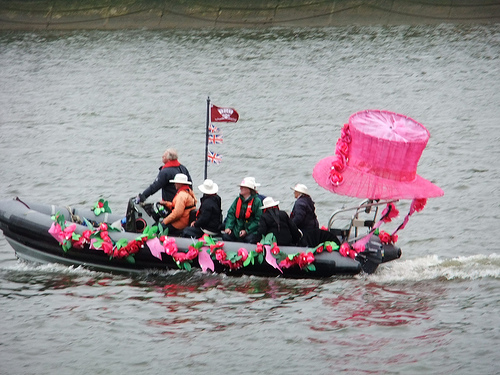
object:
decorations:
[47, 209, 357, 274]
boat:
[0, 190, 402, 277]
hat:
[169, 173, 193, 185]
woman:
[160, 173, 197, 237]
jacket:
[163, 185, 197, 230]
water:
[0, 25, 500, 375]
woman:
[223, 176, 264, 244]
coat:
[225, 193, 264, 240]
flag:
[210, 102, 239, 123]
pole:
[204, 96, 211, 180]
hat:
[312, 109, 445, 200]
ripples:
[28, 29, 371, 88]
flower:
[163, 237, 179, 255]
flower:
[64, 223, 77, 240]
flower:
[339, 242, 351, 258]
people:
[132, 148, 319, 246]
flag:
[207, 150, 223, 165]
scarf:
[162, 159, 182, 169]